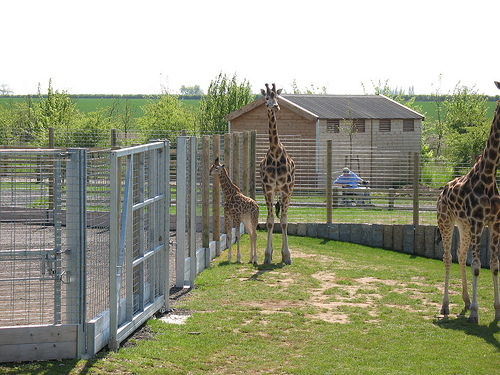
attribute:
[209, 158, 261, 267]
baby giraffe — small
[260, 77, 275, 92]
horns — tiny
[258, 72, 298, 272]
giraffe — large, adult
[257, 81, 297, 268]
giraffe — taller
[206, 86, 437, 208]
building — brick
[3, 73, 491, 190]
trees — young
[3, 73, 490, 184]
leaves — green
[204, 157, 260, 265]
giraffe — baby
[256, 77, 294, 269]
giraffe — adult